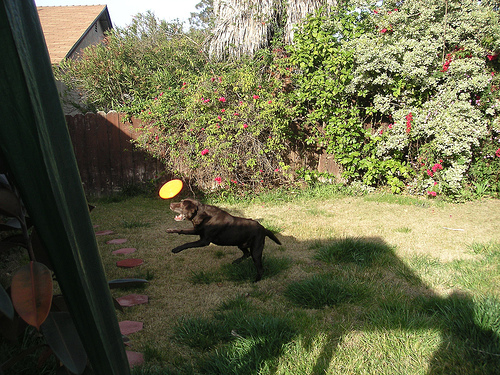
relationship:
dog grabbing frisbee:
[156, 192, 280, 283] [150, 174, 189, 204]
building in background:
[37, 0, 155, 104] [44, 0, 228, 110]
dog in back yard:
[156, 192, 280, 283] [8, 83, 498, 374]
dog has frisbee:
[156, 192, 280, 283] [150, 174, 189, 204]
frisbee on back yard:
[119, 257, 141, 269] [8, 83, 498, 374]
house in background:
[37, 0, 155, 104] [44, 0, 228, 110]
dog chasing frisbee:
[156, 192, 280, 283] [150, 174, 189, 204]